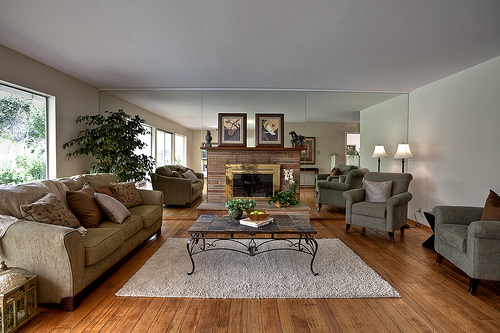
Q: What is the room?
A: Living room.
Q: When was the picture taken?
A: Daytime.